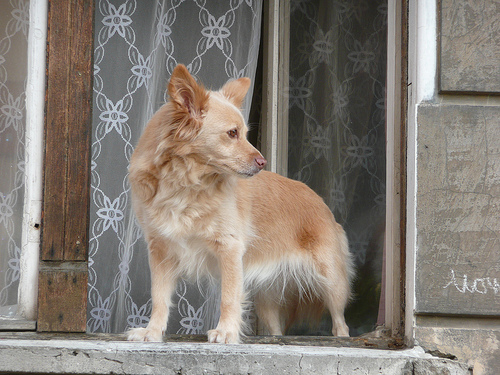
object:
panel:
[0, 318, 39, 330]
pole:
[12, 0, 48, 323]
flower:
[94, 195, 125, 235]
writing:
[439, 267, 500, 296]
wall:
[413, 0, 500, 375]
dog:
[123, 62, 358, 347]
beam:
[36, 0, 97, 334]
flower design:
[197, 10, 232, 51]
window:
[0, 0, 50, 320]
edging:
[14, 0, 48, 322]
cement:
[0, 340, 475, 375]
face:
[187, 92, 269, 181]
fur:
[256, 204, 312, 249]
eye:
[227, 128, 237, 138]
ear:
[165, 63, 207, 117]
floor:
[0, 338, 423, 359]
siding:
[414, 0, 441, 101]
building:
[0, 0, 500, 375]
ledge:
[0, 338, 475, 375]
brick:
[437, 0, 500, 96]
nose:
[253, 153, 267, 171]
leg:
[208, 242, 244, 330]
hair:
[126, 129, 230, 287]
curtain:
[86, 0, 263, 334]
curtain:
[289, 1, 389, 337]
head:
[166, 62, 266, 178]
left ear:
[215, 75, 253, 106]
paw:
[201, 326, 244, 343]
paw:
[120, 324, 163, 344]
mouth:
[218, 150, 267, 178]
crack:
[100, 356, 123, 365]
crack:
[410, 361, 417, 375]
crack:
[295, 352, 305, 375]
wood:
[385, 0, 403, 331]